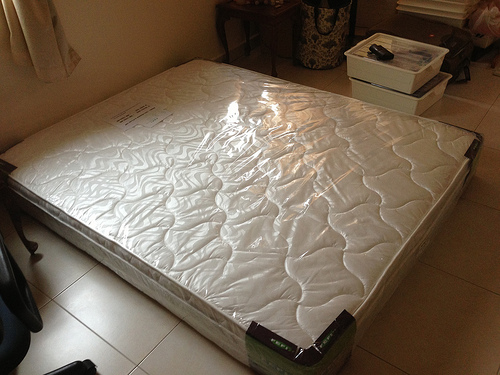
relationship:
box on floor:
[345, 70, 452, 115] [3, 12, 497, 373]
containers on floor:
[343, 33, 449, 95] [3, 12, 497, 373]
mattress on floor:
[2, 56, 485, 374] [3, 12, 497, 373]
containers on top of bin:
[343, 33, 449, 95] [345, 70, 452, 115]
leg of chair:
[27, 354, 96, 374] [0, 238, 97, 374]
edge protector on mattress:
[247, 308, 357, 375] [2, 56, 485, 374]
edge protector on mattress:
[437, 117, 487, 165] [2, 56, 485, 374]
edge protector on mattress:
[175, 54, 222, 68] [2, 56, 485, 374]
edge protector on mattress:
[2, 135, 32, 182] [2, 56, 485, 374]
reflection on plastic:
[212, 74, 295, 150] [2, 56, 485, 374]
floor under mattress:
[3, 12, 497, 373] [2, 56, 485, 374]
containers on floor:
[343, 30, 451, 119] [3, 12, 497, 373]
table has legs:
[210, 0, 306, 80] [210, 15, 303, 77]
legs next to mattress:
[210, 15, 303, 77] [2, 56, 485, 374]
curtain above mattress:
[1, 0, 85, 83] [2, 56, 485, 374]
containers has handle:
[343, 33, 449, 95] [427, 59, 447, 72]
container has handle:
[345, 70, 452, 115] [431, 82, 450, 98]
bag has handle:
[296, 2, 357, 72] [311, 3, 341, 37]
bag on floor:
[296, 2, 357, 72] [3, 12, 497, 373]